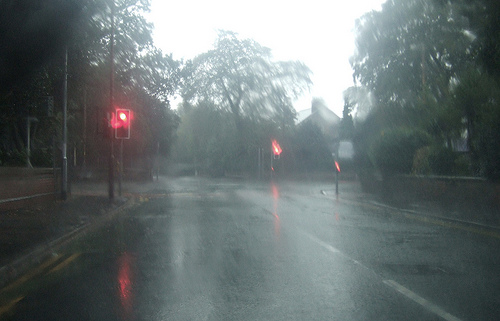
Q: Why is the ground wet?
A: It has been raining.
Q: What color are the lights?
A: Red.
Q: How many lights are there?
A: 3.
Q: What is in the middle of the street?
A: A white line.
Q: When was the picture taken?
A: Daytime.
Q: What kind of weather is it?
A: Rainy.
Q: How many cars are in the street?
A: None.